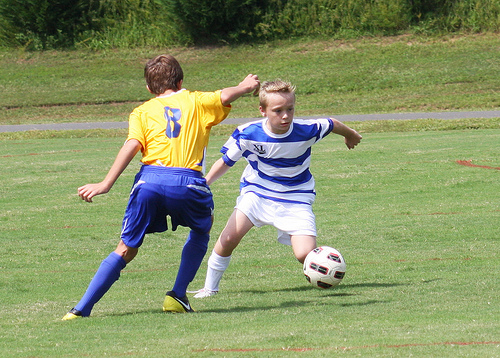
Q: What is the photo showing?
A: It is showing a field.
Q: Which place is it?
A: It is a field.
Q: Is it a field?
A: Yes, it is a field.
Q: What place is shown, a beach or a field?
A: It is a field.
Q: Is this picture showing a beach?
A: No, the picture is showing a field.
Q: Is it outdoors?
A: Yes, it is outdoors.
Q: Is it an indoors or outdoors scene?
A: It is outdoors.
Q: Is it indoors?
A: No, it is outdoors.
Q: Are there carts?
A: No, there are no carts.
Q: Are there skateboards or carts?
A: No, there are no carts or skateboards.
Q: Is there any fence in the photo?
A: No, there are no fences.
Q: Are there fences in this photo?
A: No, there are no fences.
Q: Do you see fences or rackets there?
A: No, there are no fences or rackets.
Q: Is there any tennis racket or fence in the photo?
A: No, there are no fences or rackets.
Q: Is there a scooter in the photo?
A: No, there are no scooters.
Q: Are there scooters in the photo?
A: No, there are no scooters.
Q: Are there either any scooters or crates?
A: No, there are no scooters or crates.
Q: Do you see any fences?
A: No, there are no fences.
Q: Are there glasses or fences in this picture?
A: No, there are no fences or glasses.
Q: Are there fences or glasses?
A: No, there are no fences or glasses.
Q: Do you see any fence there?
A: No, there are no fences.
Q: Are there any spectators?
A: No, there are no spectators.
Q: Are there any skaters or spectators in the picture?
A: No, there are no spectators or skaters.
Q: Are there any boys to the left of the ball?
A: Yes, there is a boy to the left of the ball.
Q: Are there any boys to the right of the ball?
A: No, the boy is to the left of the ball.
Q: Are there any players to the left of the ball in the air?
A: No, there is a boy to the left of the ball.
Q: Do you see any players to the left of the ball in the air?
A: No, there is a boy to the left of the ball.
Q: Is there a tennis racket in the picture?
A: No, there are no rackets.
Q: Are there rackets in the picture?
A: No, there are no rackets.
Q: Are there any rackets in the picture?
A: No, there are no rackets.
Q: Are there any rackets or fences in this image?
A: No, there are no rackets or fences.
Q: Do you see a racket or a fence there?
A: No, there are no rackets or fences.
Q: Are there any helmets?
A: No, there are no helmets.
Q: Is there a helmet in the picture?
A: No, there are no helmets.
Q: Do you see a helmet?
A: No, there are no helmets.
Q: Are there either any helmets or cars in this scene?
A: No, there are no helmets or cars.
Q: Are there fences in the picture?
A: No, there are no fences.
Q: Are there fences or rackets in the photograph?
A: No, there are no fences or rackets.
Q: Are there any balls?
A: Yes, there is a ball.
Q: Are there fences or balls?
A: Yes, there is a ball.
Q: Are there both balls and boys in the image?
A: Yes, there are both a ball and a boy.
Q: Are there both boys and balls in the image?
A: Yes, there are both a ball and a boy.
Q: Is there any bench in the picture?
A: No, there are no benches.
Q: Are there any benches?
A: No, there are no benches.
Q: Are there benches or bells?
A: No, there are no benches or bells.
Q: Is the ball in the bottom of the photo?
A: Yes, the ball is in the bottom of the image.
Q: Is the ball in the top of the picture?
A: No, the ball is in the bottom of the image.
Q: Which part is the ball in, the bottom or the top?
A: The ball is in the bottom of the image.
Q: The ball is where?
A: The ball is on the ground.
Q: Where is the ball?
A: The ball is on the ground.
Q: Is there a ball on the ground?
A: Yes, there is a ball on the ground.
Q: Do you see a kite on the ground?
A: No, there is a ball on the ground.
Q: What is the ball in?
A: The ball is in the air.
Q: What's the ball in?
A: The ball is in the air.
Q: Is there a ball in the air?
A: Yes, there is a ball in the air.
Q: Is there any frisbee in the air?
A: No, there is a ball in the air.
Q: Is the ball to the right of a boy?
A: Yes, the ball is to the right of a boy.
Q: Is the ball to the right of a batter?
A: No, the ball is to the right of a boy.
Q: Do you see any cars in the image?
A: No, there are no cars.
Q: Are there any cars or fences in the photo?
A: No, there are no cars or fences.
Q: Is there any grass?
A: Yes, there is grass.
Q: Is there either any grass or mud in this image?
A: Yes, there is grass.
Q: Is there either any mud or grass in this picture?
A: Yes, there is grass.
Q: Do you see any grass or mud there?
A: Yes, there is grass.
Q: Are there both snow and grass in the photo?
A: No, there is grass but no snow.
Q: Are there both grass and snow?
A: No, there is grass but no snow.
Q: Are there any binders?
A: No, there are no binders.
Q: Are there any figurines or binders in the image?
A: No, there are no binders or figurines.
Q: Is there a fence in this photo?
A: No, there are no fences.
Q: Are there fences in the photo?
A: No, there are no fences.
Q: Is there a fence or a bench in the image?
A: No, there are no fences or benches.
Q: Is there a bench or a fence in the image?
A: No, there are no fences or benches.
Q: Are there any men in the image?
A: No, there are no men.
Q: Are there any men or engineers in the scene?
A: No, there are no men or engineers.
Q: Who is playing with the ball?
A: The boy is playing with the ball.